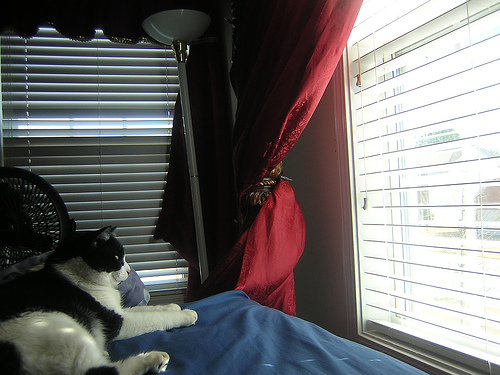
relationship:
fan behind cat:
[6, 165, 72, 255] [1, 225, 198, 373]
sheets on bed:
[107, 285, 437, 374] [96, 285, 446, 372]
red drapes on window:
[213, 0, 359, 337] [340, 0, 498, 370]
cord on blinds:
[315, 18, 390, 234] [407, 32, 497, 244]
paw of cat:
[155, 290, 207, 330] [159, 297, 209, 327]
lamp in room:
[140, 3, 235, 292] [4, 4, 499, 372]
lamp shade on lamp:
[140, 5, 210, 45] [140, 7, 215, 291]